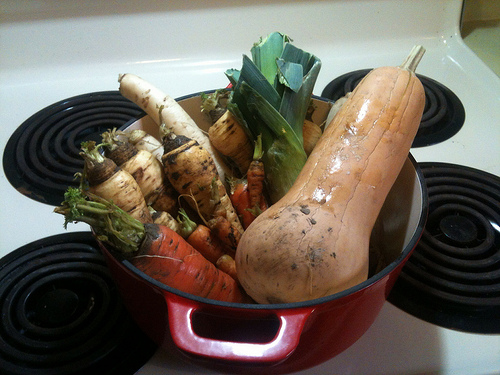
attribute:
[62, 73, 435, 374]
pot — metal, red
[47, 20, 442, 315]
vegetable — pot, root, dirty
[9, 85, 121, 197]
stove — electric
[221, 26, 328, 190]
vegetable — green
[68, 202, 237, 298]
carrot — orange, fresh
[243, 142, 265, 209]
carrot — tiny, small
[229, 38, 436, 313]
vegetable — dirty, large, fresh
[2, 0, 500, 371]
stove — white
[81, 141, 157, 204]
parsnip — white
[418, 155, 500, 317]
burner — black